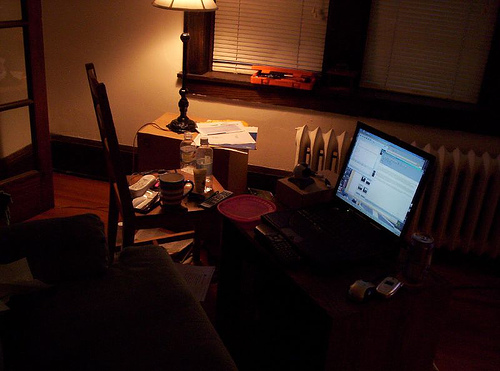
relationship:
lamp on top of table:
[149, 0, 218, 134] [135, 109, 249, 273]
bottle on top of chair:
[178, 131, 197, 187] [83, 60, 234, 279]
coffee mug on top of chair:
[157, 170, 192, 211] [83, 60, 234, 279]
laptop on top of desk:
[260, 119, 436, 266] [214, 191, 449, 370]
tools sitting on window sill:
[250, 63, 316, 92] [177, 68, 499, 118]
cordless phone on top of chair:
[129, 174, 157, 197] [83, 60, 234, 279]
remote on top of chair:
[200, 188, 233, 210] [83, 60, 234, 279]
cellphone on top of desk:
[373, 273, 403, 297] [214, 191, 449, 370]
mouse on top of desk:
[344, 277, 376, 304] [214, 191, 449, 370]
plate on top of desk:
[214, 192, 277, 224] [214, 191, 449, 370]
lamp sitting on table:
[149, 0, 218, 134] [135, 109, 249, 273]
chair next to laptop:
[83, 60, 234, 279] [260, 119, 436, 266]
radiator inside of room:
[292, 123, 499, 262] [1, 1, 497, 370]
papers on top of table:
[194, 119, 256, 151] [135, 109, 249, 273]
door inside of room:
[1, 0, 55, 227] [1, 1, 497, 370]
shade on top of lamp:
[152, 0, 219, 13] [149, 0, 218, 134]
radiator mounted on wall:
[292, 123, 499, 262] [39, 1, 499, 197]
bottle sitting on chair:
[192, 134, 213, 192] [83, 60, 234, 279]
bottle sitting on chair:
[178, 128, 197, 188] [83, 60, 234, 279]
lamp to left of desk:
[149, 0, 218, 134] [214, 191, 449, 370]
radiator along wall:
[292, 123, 499, 262] [39, 1, 499, 197]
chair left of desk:
[83, 60, 234, 279] [214, 191, 449, 370]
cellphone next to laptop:
[373, 273, 403, 297] [260, 119, 436, 266]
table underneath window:
[135, 109, 249, 273] [185, 1, 334, 96]